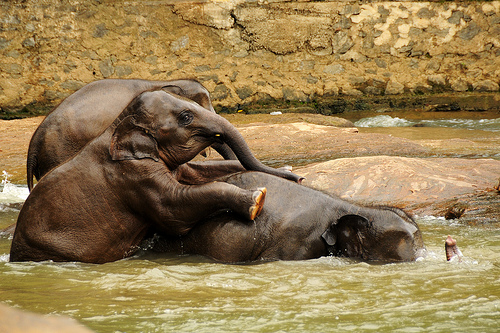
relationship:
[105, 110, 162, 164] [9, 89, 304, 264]
ear of elephant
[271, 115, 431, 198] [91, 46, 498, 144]
rock with wall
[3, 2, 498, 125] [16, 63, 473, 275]
rock behind elephants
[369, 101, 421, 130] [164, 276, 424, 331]
wave in water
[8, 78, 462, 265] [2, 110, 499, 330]
elephants in water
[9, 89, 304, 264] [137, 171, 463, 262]
elephant stepping on elephant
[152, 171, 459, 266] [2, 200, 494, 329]
elephant under water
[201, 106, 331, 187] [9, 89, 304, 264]
trunk of elephant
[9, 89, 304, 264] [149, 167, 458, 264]
elephant on elephant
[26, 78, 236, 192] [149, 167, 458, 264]
elephant on elephant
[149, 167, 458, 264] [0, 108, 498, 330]
elephant on river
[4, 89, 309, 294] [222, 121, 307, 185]
elephant has elephant trunk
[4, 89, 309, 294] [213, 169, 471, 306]
elephant on elephant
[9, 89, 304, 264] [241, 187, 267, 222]
elephant has feet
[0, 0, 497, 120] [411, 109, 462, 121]
rock around water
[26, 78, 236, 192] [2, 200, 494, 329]
elephant in water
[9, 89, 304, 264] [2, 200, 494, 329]
elephant in water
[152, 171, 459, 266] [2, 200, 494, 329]
elephant in water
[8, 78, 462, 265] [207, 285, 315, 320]
elephants in water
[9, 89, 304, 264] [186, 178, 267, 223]
elephant has feet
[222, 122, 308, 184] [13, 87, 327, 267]
elephant trunk rests on elephant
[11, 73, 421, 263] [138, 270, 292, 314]
elephants are making waves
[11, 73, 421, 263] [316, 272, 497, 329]
elephants in water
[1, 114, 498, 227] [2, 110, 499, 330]
flat rocks above water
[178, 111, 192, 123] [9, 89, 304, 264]
eye on elephant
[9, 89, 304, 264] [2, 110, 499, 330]
elephant are in water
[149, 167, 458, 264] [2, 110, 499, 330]
elephant are in water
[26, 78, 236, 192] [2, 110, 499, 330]
elephant are in water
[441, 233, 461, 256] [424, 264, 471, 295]
elephant nose emerges from water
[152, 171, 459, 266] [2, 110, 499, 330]
elephant in water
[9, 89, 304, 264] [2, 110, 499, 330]
elephant in water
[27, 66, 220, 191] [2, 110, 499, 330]
elephant in water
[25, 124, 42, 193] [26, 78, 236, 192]
tail on elephant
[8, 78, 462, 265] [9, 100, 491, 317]
elephants are in river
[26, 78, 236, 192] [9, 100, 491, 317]
elephant are in river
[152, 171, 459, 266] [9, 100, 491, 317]
elephant are in river